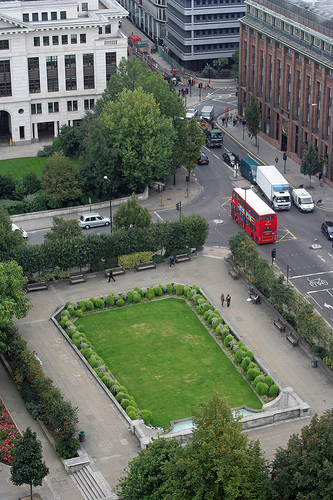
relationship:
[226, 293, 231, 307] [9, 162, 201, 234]
person walking on sidewalk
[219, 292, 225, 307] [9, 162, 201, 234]
person walking on sidewalk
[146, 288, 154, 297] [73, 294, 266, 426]
bush around grass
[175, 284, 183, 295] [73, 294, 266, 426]
bush around grass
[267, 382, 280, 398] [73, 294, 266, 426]
bush around grass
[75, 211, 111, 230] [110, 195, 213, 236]
car in street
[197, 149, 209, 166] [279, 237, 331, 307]
car in street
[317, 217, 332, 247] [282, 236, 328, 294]
car in street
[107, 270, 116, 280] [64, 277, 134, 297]
pedestrian on sidewalk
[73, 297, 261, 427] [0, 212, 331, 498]
grass in park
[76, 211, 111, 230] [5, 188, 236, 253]
car on street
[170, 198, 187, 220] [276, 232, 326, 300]
stoplight in street